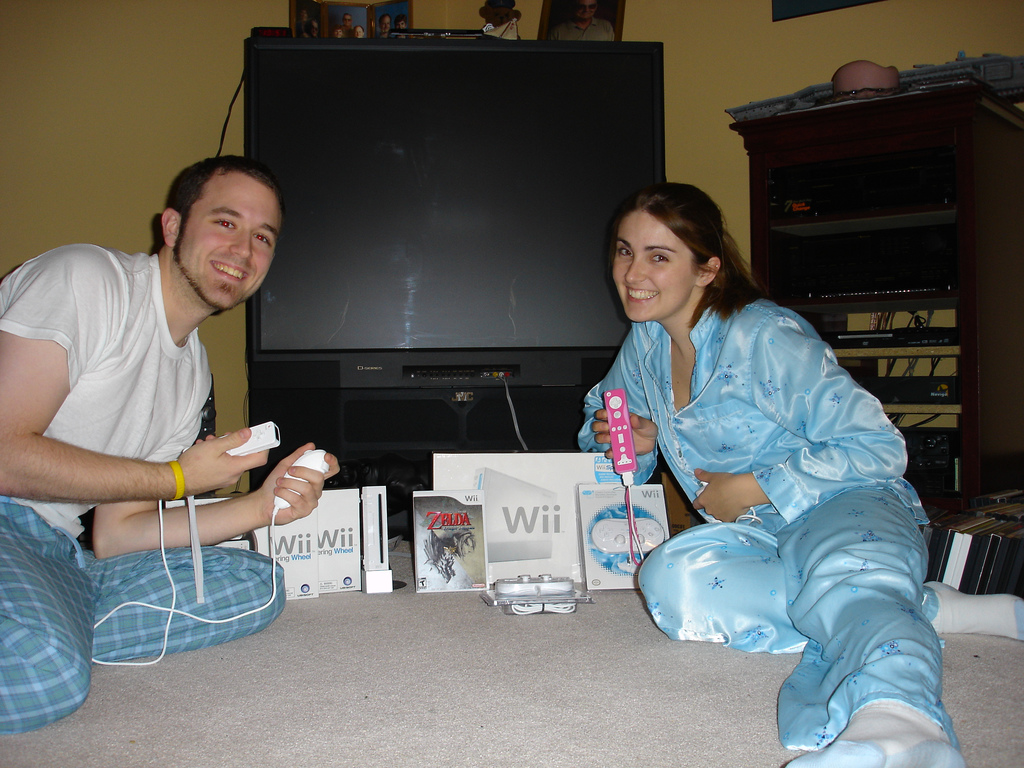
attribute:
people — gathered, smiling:
[5, 145, 980, 754]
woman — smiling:
[526, 161, 978, 731]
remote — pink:
[594, 385, 654, 492]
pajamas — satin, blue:
[566, 319, 948, 729]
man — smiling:
[3, 129, 359, 722]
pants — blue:
[2, 504, 309, 733]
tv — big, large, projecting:
[220, 18, 734, 482]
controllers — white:
[488, 467, 685, 634]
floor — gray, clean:
[17, 530, 1021, 763]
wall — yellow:
[2, 3, 766, 408]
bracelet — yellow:
[164, 455, 191, 505]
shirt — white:
[10, 234, 235, 543]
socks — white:
[845, 559, 1005, 767]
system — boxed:
[417, 441, 647, 597]